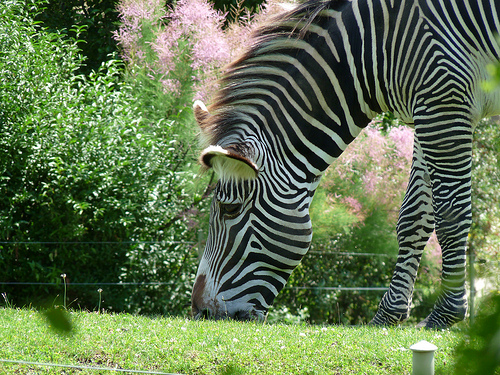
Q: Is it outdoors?
A: Yes, it is outdoors.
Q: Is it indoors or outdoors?
A: It is outdoors.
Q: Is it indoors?
A: No, it is outdoors.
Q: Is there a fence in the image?
A: Yes, there is a fence.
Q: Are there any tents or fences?
A: Yes, there is a fence.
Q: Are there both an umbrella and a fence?
A: No, there is a fence but no umbrellas.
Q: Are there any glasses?
A: No, there are no glasses.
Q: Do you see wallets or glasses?
A: No, there are no glasses or wallets.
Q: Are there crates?
A: No, there are no crates.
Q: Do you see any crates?
A: No, there are no crates.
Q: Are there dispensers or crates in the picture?
A: No, there are no crates or dispensers.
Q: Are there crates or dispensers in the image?
A: No, there are no crates or dispensers.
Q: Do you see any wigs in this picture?
A: No, there are no wigs.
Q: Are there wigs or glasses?
A: No, there are no wigs or glasses.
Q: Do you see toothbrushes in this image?
A: No, there are no toothbrushes.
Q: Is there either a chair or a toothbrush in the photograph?
A: No, there are no toothbrushes or chairs.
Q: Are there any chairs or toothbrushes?
A: No, there are no toothbrushes or chairs.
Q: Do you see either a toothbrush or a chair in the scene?
A: No, there are no toothbrushes or chairs.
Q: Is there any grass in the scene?
A: Yes, there is grass.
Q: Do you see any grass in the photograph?
A: Yes, there is grass.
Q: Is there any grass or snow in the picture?
A: Yes, there is grass.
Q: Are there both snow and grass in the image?
A: No, there is grass but no snow.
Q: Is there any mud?
A: No, there is no mud.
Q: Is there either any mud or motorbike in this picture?
A: No, there are no mud or motorcycles.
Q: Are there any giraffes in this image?
A: No, there are no giraffes.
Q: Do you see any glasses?
A: No, there are no glasses.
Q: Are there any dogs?
A: No, there are no dogs.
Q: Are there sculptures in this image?
A: No, there are no sculptures.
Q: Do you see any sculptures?
A: No, there are no sculptures.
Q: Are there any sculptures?
A: No, there are no sculptures.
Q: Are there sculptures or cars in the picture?
A: No, there are no sculptures or cars.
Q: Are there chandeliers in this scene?
A: No, there are no chandeliers.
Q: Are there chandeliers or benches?
A: No, there are no chandeliers or benches.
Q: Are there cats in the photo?
A: No, there are no cats.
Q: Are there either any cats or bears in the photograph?
A: No, there are no cats or bears.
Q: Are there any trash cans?
A: No, there are no trash cans.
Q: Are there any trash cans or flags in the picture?
A: No, there are no trash cans or flags.